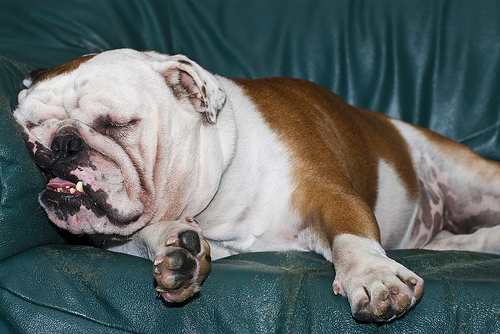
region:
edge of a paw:
[163, 252, 188, 292]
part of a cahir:
[233, 263, 286, 325]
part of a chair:
[251, 280, 291, 322]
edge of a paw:
[181, 273, 198, 296]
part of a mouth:
[51, 165, 95, 215]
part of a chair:
[231, 248, 274, 294]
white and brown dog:
[24, 35, 496, 315]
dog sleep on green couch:
[2, 3, 497, 330]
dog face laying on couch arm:
[0, 48, 207, 235]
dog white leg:
[321, 233, 443, 328]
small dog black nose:
[45, 121, 92, 164]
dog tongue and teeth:
[40, 164, 94, 214]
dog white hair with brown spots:
[141, 42, 231, 122]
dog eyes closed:
[19, 91, 146, 148]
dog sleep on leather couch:
[0, 0, 499, 332]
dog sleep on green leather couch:
[4, 0, 489, 328]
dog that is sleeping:
[15, 45, 499, 325]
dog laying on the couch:
[9, 38, 499, 328]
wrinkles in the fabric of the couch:
[314, 31, 467, 121]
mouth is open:
[37, 161, 94, 208]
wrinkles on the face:
[74, 121, 156, 188]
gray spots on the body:
[410, 157, 489, 262]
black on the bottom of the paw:
[162, 231, 215, 286]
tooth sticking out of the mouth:
[72, 177, 89, 195]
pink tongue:
[47, 173, 80, 198]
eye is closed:
[96, 109, 153, 136]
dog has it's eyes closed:
[90, 90, 148, 134]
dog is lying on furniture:
[205, 217, 322, 292]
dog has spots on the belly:
[422, 158, 444, 248]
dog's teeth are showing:
[65, 170, 87, 193]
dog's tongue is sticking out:
[41, 176, 81, 189]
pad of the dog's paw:
[182, 241, 214, 289]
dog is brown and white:
[248, 78, 324, 200]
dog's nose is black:
[50, 127, 75, 158]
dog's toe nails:
[151, 242, 166, 292]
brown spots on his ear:
[184, 66, 225, 113]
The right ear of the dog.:
[169, 58, 222, 124]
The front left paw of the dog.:
[152, 227, 218, 302]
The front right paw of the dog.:
[323, 261, 426, 326]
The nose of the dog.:
[50, 132, 84, 161]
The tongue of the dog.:
[45, 171, 73, 190]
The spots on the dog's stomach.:
[415, 170, 440, 244]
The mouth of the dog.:
[43, 170, 85, 205]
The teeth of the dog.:
[51, 180, 86, 194]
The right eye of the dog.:
[105, 110, 132, 137]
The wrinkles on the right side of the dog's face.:
[117, 145, 164, 233]